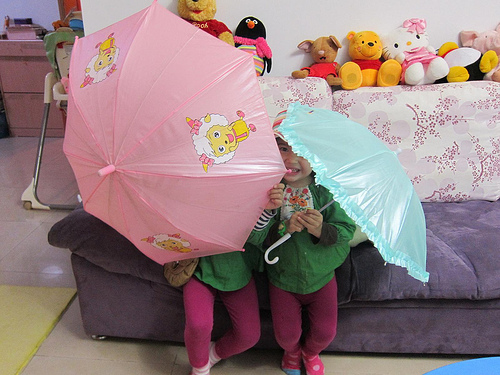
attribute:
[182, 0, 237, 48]
stuffed animal — toy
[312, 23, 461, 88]
animals — stuffed, group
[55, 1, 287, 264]
umbrella — large, open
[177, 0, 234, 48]
stuffed animal — toy